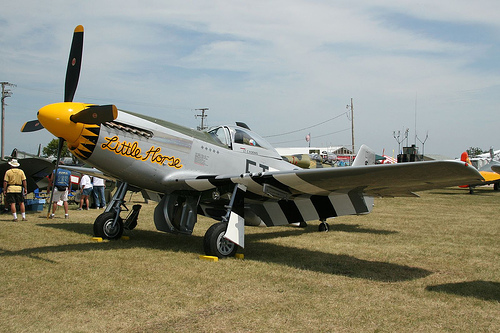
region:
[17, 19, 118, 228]
the propellers of the airplane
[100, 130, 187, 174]
the cursive writing on the plane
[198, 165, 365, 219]
the black and white stripes on the airplane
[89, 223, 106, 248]
the yellow blocks by the tire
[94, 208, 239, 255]
the wheels of the airplane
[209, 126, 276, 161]
the cockpit windshield on the airplane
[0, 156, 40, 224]
the man standing in the grass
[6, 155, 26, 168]
the white hat on the mans head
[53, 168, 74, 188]
the bag on the mans back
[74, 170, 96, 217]
the women crouthcing behind the plane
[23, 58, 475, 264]
plane on the ground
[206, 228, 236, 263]
wheel on the plane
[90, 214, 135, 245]
wheel on the plane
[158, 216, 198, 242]
wheel on the plane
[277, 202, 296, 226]
stripe on the plane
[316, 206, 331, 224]
stripe on the plane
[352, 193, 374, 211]
stripe on the plane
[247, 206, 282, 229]
stripe on the plane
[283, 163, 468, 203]
wing of the plane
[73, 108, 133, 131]
blade of the plane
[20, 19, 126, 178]
black propeller with yellow tips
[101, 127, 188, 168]
yellow and black cursive letters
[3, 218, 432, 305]
shadow of plane on grass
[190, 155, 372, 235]
black and white stripes on wing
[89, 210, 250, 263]
yellow blocks under wheels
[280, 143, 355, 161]
white roof in background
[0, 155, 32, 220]
man in yellow shirt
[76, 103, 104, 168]
black and yellow triangle design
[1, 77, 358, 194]
wires and utility poles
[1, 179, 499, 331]
greenish brown grass under plane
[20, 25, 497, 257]
white and yellow airplane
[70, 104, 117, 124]
propeller of plane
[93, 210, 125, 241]
front wheel of the plane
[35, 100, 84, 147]
yellow nose of the plane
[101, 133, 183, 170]
name of the plane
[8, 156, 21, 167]
floppy hat on man's head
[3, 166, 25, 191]
man wearing a yellow shirt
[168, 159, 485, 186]
left wing of the plane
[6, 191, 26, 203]
black shorts' the man is wearing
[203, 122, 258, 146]
cockpit of the plane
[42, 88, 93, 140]
yellow nose on plane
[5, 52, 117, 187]
plane has black propellers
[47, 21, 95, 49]
yellow stripes on propeller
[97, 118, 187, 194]
yellow name on plane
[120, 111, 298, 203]
plane has grey body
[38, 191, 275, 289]
black wheels on plane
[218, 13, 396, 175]
blue and white sky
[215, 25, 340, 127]
layered white clouds in sky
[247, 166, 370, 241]
black and white stripes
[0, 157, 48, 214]
man has yellow shirt